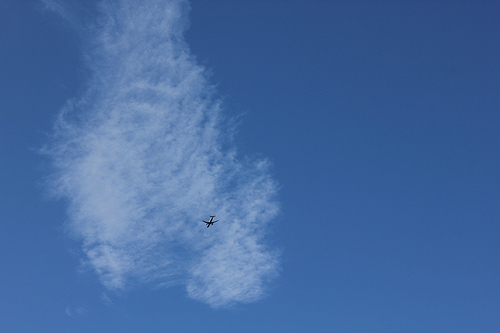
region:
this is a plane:
[203, 211, 219, 231]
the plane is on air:
[202, 208, 224, 230]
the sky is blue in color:
[284, 0, 486, 144]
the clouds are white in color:
[106, 62, 188, 241]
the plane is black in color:
[199, 209, 219, 230]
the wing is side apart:
[200, 216, 208, 224]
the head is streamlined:
[204, 226, 211, 229]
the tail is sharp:
[211, 213, 216, 219]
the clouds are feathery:
[101, 58, 204, 203]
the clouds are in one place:
[89, 16, 201, 206]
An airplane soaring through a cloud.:
[16, 37, 460, 323]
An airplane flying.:
[20, 39, 435, 321]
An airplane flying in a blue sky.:
[22, 26, 442, 322]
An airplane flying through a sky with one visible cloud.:
[17, 18, 447, 321]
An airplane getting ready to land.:
[18, 18, 437, 324]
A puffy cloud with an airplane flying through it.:
[14, 12, 426, 325]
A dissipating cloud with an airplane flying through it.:
[12, 15, 435, 325]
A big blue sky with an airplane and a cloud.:
[15, 15, 395, 325]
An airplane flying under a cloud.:
[10, 5, 415, 320]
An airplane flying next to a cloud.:
[5, 10, 395, 320]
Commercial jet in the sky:
[176, 177, 252, 269]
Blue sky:
[339, 58, 449, 233]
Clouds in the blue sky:
[67, 113, 394, 249]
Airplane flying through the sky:
[176, 167, 258, 290]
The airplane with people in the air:
[125, 136, 317, 325]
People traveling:
[156, 210, 299, 294]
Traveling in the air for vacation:
[137, 165, 342, 294]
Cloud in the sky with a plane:
[74, 78, 281, 328]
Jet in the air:
[186, 161, 263, 250]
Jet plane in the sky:
[175, 162, 257, 258]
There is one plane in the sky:
[15, 37, 436, 326]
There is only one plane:
[69, 138, 464, 323]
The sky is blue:
[28, 18, 433, 331]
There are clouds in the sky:
[43, 10, 447, 321]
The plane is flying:
[38, 75, 390, 330]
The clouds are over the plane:
[61, 96, 354, 322]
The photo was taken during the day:
[33, 59, 473, 330]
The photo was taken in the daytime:
[25, 16, 468, 313]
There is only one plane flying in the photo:
[48, 13, 441, 302]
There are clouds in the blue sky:
[33, 13, 430, 315]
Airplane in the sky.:
[202, 212, 216, 229]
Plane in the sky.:
[201, 211, 217, 231]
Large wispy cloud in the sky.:
[39, 1, 283, 309]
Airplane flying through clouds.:
[202, 213, 215, 228]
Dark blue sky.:
[330, 103, 415, 213]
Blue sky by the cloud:
[197, 7, 292, 55]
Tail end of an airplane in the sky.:
[209, 213, 216, 220]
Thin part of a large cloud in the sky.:
[202, 240, 282, 311]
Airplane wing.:
[201, 214, 208, 228]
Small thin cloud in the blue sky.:
[60, 302, 84, 321]